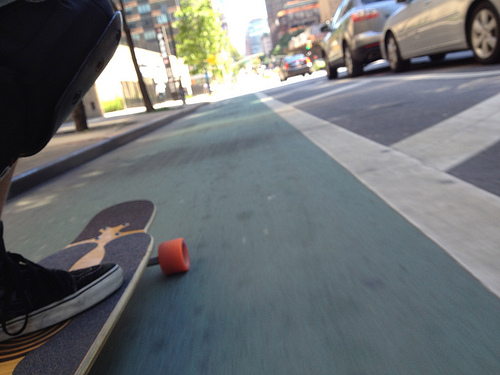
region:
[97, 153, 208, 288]
Wheel on the skateboard.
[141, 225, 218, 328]
Red wheel on the skateboard.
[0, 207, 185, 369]
Skateboard on the road.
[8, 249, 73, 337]
Laces on the shoes.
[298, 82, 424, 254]
White stripe on the road.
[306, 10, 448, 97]
Cars on the road.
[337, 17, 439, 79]
Wheels on the cars.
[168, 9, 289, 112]
Trees in the background.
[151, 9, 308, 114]
Green tree in the background.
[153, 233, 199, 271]
orange wheel on skateboard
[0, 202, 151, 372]
black and yellow skateboard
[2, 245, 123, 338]
black shoe on skateboarder's foot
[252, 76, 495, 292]
white lines painted in street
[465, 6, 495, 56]
back left tire on car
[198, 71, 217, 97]
person standing in the street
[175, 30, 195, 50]
leaves on the tree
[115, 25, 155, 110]
telephone pole on the sidewalk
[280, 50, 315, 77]
car parked on the street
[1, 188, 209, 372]
Person on a skateboard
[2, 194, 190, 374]
Person is on a skateboard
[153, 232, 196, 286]
Skateboard with orange wheels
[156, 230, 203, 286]
Skateboard has orange wheels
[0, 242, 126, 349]
Person wearing shoes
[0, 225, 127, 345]
Person is wearing shoes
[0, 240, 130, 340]
Person wearing black and white shoes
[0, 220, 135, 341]
Person is wearing black and white shoes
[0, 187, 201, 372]
Person skateboarding in the middle of the street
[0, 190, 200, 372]
Person skateboarding in the middle of the road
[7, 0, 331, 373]
a skateboarder going down a street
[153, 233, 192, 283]
the skateboard has red wheels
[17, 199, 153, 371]
the skateboard is black with a design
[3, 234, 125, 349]
a skateboarder's shoe is black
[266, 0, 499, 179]
the street has vehicular traffic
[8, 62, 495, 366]
the skateboarder is traveling on a bike path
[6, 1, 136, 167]
the skateboarder has protective knee pads on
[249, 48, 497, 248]
white lines are on the street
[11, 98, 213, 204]
a curb is on the side of the bike path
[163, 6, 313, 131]
a green tree is on the side of the street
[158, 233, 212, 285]
wheel on the skateboard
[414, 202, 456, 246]
white on the line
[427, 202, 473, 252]
white on the line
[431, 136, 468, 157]
white on the line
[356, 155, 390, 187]
white on the line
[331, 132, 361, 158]
white on the line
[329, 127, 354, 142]
white on the line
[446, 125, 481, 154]
white on the line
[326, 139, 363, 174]
white on the line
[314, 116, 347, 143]
white on the line